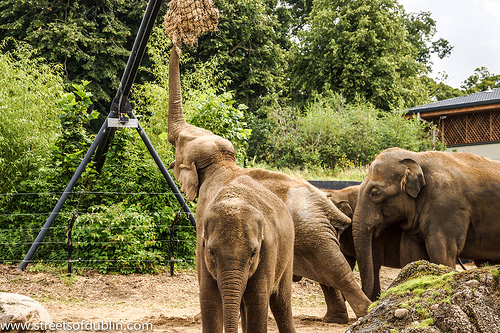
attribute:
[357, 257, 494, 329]
moss — green, grey, mossy, gray, white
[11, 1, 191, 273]
tripod — metal, triangular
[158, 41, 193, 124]
trunk — gray, log, extended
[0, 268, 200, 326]
ground — brown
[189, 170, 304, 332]
elephant — brown, african, baby, indian, small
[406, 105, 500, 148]
panel — wood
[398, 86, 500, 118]
roof — black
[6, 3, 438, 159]
trees — green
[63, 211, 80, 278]
poles — metal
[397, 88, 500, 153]
house — wooden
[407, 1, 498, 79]
sky — cloudy, white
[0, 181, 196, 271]
fence — barbed wire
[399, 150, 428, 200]
ear — gray